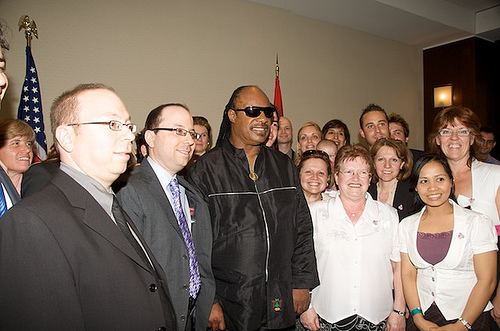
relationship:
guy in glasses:
[0, 82, 179, 329] [59, 108, 153, 140]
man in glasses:
[116, 102, 217, 330] [138, 110, 207, 145]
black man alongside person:
[185, 85, 321, 329] [294, 143, 406, 330]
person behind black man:
[297, 149, 335, 205] [185, 85, 321, 329]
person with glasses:
[294, 143, 406, 330] [331, 155, 371, 181]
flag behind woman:
[16, 44, 46, 166] [0, 116, 35, 215]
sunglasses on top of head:
[297, 147, 332, 159] [302, 149, 331, 194]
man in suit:
[116, 102, 217, 330] [115, 160, 215, 329]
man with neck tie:
[116, 102, 217, 330] [166, 177, 201, 299]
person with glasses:
[294, 143, 406, 330] [337, 160, 372, 182]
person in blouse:
[294, 143, 406, 330] [306, 191, 403, 325]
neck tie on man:
[166, 177, 201, 299] [116, 102, 217, 330]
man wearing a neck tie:
[116, 102, 217, 330] [166, 177, 201, 299]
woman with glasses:
[424, 102, 499, 227] [437, 126, 471, 138]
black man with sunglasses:
[185, 85, 321, 329] [231, 105, 275, 119]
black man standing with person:
[185, 85, 321, 329] [297, 145, 331, 204]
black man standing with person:
[185, 85, 321, 329] [306, 142, 404, 331]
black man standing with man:
[185, 85, 321, 329] [116, 102, 217, 330]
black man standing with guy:
[185, 85, 321, 329] [0, 82, 179, 329]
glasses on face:
[243, 104, 276, 118] [235, 88, 269, 145]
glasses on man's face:
[156, 116, 205, 145] [41, 110, 159, 133]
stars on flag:
[17, 70, 72, 138] [10, 26, 64, 136]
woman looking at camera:
[428, 105, 499, 238] [319, 142, 484, 253]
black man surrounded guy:
[198, 84, 319, 329] [0, 82, 179, 329]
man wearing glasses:
[116, 102, 217, 330] [145, 126, 197, 138]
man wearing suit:
[116, 102, 217, 330] [5, 162, 182, 329]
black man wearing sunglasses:
[185, 85, 321, 329] [229, 101, 277, 120]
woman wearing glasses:
[428, 105, 499, 238] [428, 114, 499, 141]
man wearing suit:
[129, 97, 236, 330] [115, 160, 215, 329]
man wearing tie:
[129, 97, 236, 330] [166, 173, 210, 306]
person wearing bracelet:
[294, 143, 406, 330] [410, 304, 432, 319]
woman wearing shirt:
[367, 140, 418, 214] [378, 184, 395, 205]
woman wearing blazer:
[367, 140, 418, 214] [369, 177, 419, 218]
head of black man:
[224, 84, 277, 146] [185, 85, 321, 329]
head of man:
[143, 102, 195, 173] [473, 124, 499, 163]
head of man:
[49, 82, 135, 187] [116, 102, 217, 330]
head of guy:
[357, 102, 389, 146] [0, 82, 179, 329]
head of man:
[477, 127, 497, 152] [275, 115, 298, 157]